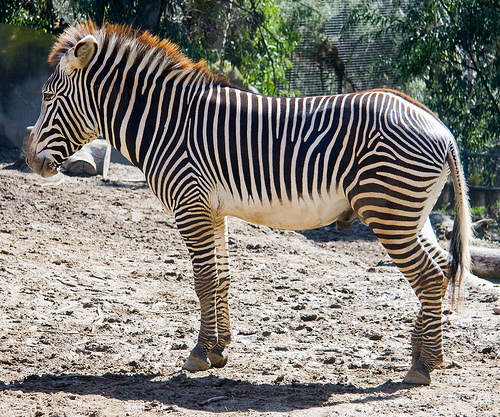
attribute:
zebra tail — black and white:
[432, 127, 478, 311]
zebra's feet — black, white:
[180, 350, 213, 371]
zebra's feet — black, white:
[206, 346, 228, 368]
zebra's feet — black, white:
[399, 365, 433, 387]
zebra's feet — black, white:
[417, 345, 445, 368]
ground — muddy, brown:
[0, 156, 500, 415]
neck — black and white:
[98, 42, 153, 177]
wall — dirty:
[396, 142, 425, 167]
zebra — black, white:
[22, 13, 476, 392]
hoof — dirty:
[183, 342, 214, 374]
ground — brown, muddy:
[18, 185, 113, 357]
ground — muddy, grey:
[53, 279, 175, 384]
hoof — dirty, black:
[406, 356, 433, 384]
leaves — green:
[235, 7, 294, 90]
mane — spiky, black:
[38, 17, 228, 85]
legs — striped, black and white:
[167, 202, 239, 378]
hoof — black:
[212, 343, 227, 371]